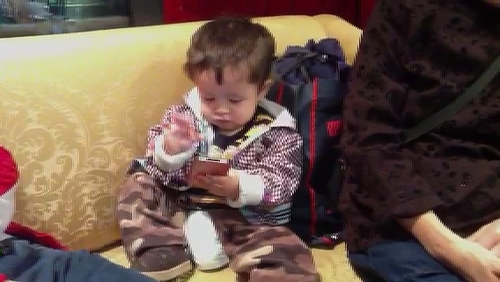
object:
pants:
[206, 203, 323, 282]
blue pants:
[344, 236, 464, 282]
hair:
[175, 15, 282, 83]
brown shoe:
[133, 258, 192, 282]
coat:
[125, 85, 305, 224]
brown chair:
[0, 12, 366, 282]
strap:
[401, 58, 500, 154]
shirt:
[341, 0, 500, 256]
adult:
[339, 0, 500, 282]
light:
[0, 39, 100, 58]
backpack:
[263, 37, 350, 249]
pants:
[116, 166, 190, 262]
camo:
[117, 171, 189, 264]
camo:
[212, 211, 320, 282]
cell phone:
[188, 156, 228, 187]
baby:
[114, 15, 318, 280]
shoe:
[128, 245, 195, 282]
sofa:
[0, 10, 362, 282]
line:
[310, 76, 317, 232]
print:
[18, 72, 115, 204]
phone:
[187, 156, 227, 194]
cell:
[190, 156, 230, 188]